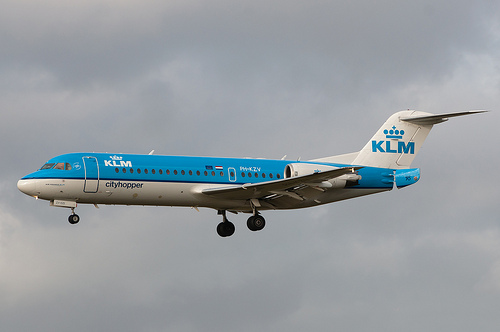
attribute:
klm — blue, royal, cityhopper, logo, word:
[371, 139, 416, 155]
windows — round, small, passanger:
[137, 168, 143, 176]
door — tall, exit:
[82, 158, 104, 194]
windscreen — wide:
[41, 161, 75, 171]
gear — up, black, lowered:
[62, 201, 268, 237]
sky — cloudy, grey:
[1, 10, 499, 330]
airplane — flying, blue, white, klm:
[27, 105, 486, 236]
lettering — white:
[105, 156, 134, 170]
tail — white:
[308, 87, 491, 166]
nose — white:
[14, 173, 38, 203]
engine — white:
[283, 163, 364, 187]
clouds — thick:
[10, 0, 482, 106]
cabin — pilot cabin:
[32, 155, 78, 177]